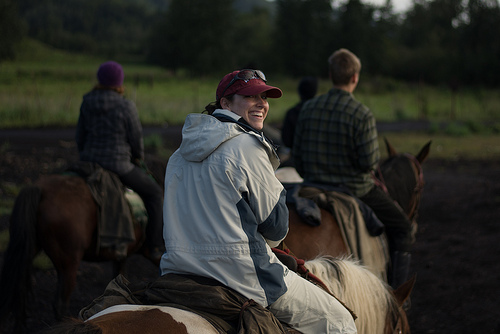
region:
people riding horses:
[1, 40, 432, 332]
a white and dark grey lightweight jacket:
[158, 113, 298, 296]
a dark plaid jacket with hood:
[73, 89, 145, 175]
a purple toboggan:
[96, 63, 122, 89]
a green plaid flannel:
[294, 90, 383, 196]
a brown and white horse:
[69, 255, 410, 330]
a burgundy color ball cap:
[214, 69, 281, 100]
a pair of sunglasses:
[228, 66, 273, 86]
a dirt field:
[4, 118, 499, 328]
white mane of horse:
[304, 254, 396, 331]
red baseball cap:
[205, 64, 285, 104]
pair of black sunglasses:
[215, 66, 267, 96]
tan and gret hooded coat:
[153, 104, 293, 311]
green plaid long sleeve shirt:
[293, 85, 379, 196]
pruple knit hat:
[84, 56, 124, 88]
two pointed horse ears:
[377, 130, 437, 165]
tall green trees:
[1, 0, 494, 100]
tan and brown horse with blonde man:
[47, 250, 422, 331]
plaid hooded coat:
[66, 85, 146, 175]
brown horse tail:
[2, 176, 47, 292]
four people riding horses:
[48, 39, 483, 330]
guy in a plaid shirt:
[295, 50, 425, 257]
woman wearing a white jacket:
[151, 57, 311, 328]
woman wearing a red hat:
[156, 61, 316, 327]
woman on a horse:
[1, 15, 161, 310]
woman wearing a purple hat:
[62, 57, 153, 232]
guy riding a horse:
[290, 41, 430, 282]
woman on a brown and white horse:
[85, 62, 405, 327]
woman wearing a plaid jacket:
[71, 55, 159, 280]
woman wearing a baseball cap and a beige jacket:
[193, 68, 290, 280]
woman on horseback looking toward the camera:
[173, 64, 321, 328]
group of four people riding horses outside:
[81, 50, 407, 318]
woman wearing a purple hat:
[78, 65, 160, 222]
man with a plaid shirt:
[306, 50, 404, 237]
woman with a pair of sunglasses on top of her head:
[221, 65, 269, 130]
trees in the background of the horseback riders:
[22, 0, 464, 47]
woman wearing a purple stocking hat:
[81, 63, 138, 164]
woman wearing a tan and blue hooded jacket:
[178, 68, 291, 295]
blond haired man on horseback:
[323, 49, 380, 201]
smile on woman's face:
[236, 103, 293, 123]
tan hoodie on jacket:
[151, 108, 253, 175]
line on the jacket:
[236, 163, 302, 218]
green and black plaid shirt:
[302, 108, 372, 160]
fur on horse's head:
[311, 255, 378, 303]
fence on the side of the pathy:
[397, 74, 447, 122]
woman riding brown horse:
[66, 54, 168, 209]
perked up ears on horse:
[383, 134, 453, 166]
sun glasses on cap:
[226, 56, 291, 82]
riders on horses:
[82, 52, 400, 265]